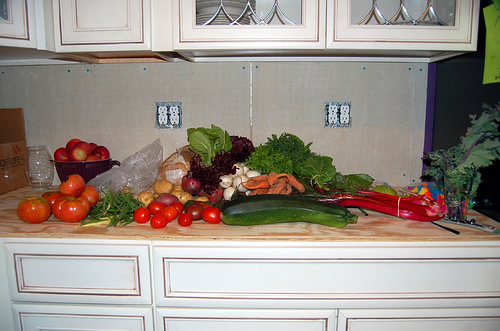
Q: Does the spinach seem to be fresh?
A: Yes, the spinach is fresh.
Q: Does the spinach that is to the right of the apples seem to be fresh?
A: Yes, the spinach is fresh.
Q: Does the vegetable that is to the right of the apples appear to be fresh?
A: Yes, the spinach is fresh.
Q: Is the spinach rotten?
A: No, the spinach is fresh.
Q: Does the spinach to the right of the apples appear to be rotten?
A: No, the spinach is fresh.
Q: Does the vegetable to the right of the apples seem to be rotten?
A: No, the spinach is fresh.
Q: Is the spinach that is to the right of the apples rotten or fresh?
A: The spinach is fresh.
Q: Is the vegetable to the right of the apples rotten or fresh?
A: The spinach is fresh.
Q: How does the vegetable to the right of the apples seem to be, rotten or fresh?
A: The spinach is fresh.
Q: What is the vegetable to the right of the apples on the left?
A: The vegetable is spinach.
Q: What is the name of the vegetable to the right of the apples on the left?
A: The vegetable is spinach.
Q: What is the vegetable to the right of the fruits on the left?
A: The vegetable is spinach.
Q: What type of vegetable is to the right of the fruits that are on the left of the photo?
A: The vegetable is spinach.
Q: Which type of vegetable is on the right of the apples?
A: The vegetable is spinach.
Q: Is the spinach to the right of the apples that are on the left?
A: Yes, the spinach is to the right of the apples.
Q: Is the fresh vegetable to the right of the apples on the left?
A: Yes, the spinach is to the right of the apples.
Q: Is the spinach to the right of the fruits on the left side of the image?
A: Yes, the spinach is to the right of the apples.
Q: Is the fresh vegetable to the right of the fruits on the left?
A: Yes, the spinach is to the right of the apples.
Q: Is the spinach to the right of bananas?
A: No, the spinach is to the right of the apples.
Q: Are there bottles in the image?
A: No, there are no bottles.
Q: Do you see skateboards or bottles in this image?
A: No, there are no bottles or skateboards.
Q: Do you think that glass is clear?
A: Yes, the glass is clear.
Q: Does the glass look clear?
A: Yes, the glass is clear.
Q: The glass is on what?
A: The glass is on the counter.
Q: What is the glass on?
A: The glass is on the counter.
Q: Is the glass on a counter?
A: Yes, the glass is on a counter.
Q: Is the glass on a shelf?
A: No, the glass is on a counter.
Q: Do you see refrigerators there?
A: Yes, there is a refrigerator.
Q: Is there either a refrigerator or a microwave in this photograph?
A: Yes, there is a refrigerator.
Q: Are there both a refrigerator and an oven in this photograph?
A: No, there is a refrigerator but no ovens.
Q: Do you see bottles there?
A: No, there are no bottles.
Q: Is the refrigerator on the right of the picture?
A: Yes, the refrigerator is on the right of the image.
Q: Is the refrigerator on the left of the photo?
A: No, the refrigerator is on the right of the image.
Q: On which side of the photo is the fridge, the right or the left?
A: The fridge is on the right of the image.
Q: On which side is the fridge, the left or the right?
A: The fridge is on the right of the image.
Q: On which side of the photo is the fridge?
A: The fridge is on the right of the image.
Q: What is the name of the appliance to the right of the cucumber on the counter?
A: The appliance is a refrigerator.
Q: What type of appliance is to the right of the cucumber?
A: The appliance is a refrigerator.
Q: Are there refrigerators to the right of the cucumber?
A: Yes, there is a refrigerator to the right of the cucumber.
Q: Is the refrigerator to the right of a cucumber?
A: Yes, the refrigerator is to the right of a cucumber.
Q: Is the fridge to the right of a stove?
A: No, the fridge is to the right of a cucumber.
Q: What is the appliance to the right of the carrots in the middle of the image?
A: The appliance is a refrigerator.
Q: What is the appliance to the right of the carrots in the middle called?
A: The appliance is a refrigerator.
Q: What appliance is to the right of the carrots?
A: The appliance is a refrigerator.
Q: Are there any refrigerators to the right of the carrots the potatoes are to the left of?
A: Yes, there is a refrigerator to the right of the carrots.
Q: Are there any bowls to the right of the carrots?
A: No, there is a refrigerator to the right of the carrots.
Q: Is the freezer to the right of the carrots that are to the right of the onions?
A: Yes, the freezer is to the right of the carrots.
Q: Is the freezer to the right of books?
A: No, the freezer is to the right of the carrots.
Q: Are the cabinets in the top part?
A: Yes, the cabinets are in the top of the image.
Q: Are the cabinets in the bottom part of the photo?
A: No, the cabinets are in the top of the image.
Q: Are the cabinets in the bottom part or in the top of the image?
A: The cabinets are in the top of the image.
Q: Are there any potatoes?
A: Yes, there are potatoes.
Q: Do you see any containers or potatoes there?
A: Yes, there are potatoes.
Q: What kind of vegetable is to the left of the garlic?
A: The vegetables are potatoes.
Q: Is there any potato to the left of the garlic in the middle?
A: Yes, there are potatoes to the left of the garlic.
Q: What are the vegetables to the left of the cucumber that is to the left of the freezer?
A: The vegetables are potatoes.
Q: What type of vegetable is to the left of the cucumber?
A: The vegetables are potatoes.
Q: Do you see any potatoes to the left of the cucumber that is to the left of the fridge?
A: Yes, there are potatoes to the left of the cucumber.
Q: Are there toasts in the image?
A: No, there are no toasts.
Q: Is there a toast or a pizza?
A: No, there are no toasts or pizzas.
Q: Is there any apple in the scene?
A: Yes, there are apples.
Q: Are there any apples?
A: Yes, there are apples.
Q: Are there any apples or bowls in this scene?
A: Yes, there are apples.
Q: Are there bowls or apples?
A: Yes, there are apples.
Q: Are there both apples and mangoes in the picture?
A: No, there are apples but no mangoes.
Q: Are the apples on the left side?
A: Yes, the apples are on the left of the image.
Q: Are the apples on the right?
A: No, the apples are on the left of the image.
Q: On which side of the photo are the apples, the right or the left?
A: The apples are on the left of the image.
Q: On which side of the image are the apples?
A: The apples are on the left of the image.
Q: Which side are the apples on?
A: The apples are on the left of the image.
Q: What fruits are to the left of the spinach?
A: The fruits are apples.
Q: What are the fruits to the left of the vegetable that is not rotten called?
A: The fruits are apples.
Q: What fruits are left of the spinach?
A: The fruits are apples.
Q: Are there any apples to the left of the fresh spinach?
A: Yes, there are apples to the left of the spinach.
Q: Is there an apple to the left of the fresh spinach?
A: Yes, there are apples to the left of the spinach.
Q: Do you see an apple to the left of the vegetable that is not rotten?
A: Yes, there are apples to the left of the spinach.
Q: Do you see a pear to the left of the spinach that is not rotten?
A: No, there are apples to the left of the spinach.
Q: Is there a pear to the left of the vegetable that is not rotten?
A: No, there are apples to the left of the spinach.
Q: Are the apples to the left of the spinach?
A: Yes, the apples are to the left of the spinach.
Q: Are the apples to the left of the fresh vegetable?
A: Yes, the apples are to the left of the spinach.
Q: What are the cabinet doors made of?
A: The cabinet doors are made of glass.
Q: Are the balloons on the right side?
A: Yes, the balloons are on the right of the image.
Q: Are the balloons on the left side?
A: No, the balloons are on the right of the image.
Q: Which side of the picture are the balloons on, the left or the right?
A: The balloons are on the right of the image.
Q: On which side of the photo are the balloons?
A: The balloons are on the right of the image.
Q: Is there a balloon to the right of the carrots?
A: Yes, there are balloons to the right of the carrots.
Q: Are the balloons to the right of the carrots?
A: Yes, the balloons are to the right of the carrots.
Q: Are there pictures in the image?
A: No, there are no pictures.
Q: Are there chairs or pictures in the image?
A: No, there are no pictures or chairs.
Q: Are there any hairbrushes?
A: No, there are no hairbrushes.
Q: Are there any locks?
A: No, there are no locks.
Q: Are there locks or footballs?
A: No, there are no locks or footballs.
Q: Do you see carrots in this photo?
A: Yes, there are carrots.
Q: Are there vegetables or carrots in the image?
A: Yes, there are carrots.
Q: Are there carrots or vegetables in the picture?
A: Yes, there are carrots.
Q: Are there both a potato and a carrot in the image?
A: Yes, there are both a carrot and a potato.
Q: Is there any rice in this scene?
A: No, there is no rice.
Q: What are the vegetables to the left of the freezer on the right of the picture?
A: The vegetables are carrots.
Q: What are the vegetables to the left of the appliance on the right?
A: The vegetables are carrots.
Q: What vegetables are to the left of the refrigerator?
A: The vegetables are carrots.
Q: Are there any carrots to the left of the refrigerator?
A: Yes, there are carrots to the left of the refrigerator.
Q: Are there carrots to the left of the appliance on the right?
A: Yes, there are carrots to the left of the refrigerator.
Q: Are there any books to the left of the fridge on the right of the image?
A: No, there are carrots to the left of the freezer.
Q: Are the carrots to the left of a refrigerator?
A: Yes, the carrots are to the left of a refrigerator.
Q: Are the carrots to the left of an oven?
A: No, the carrots are to the left of a refrigerator.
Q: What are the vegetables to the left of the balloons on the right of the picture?
A: The vegetables are carrots.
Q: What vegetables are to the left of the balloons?
A: The vegetables are carrots.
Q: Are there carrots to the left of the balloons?
A: Yes, there are carrots to the left of the balloons.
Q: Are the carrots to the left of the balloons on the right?
A: Yes, the carrots are to the left of the balloons.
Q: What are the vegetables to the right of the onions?
A: The vegetables are carrots.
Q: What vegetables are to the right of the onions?
A: The vegetables are carrots.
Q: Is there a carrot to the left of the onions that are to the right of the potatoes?
A: No, the carrots are to the right of the onions.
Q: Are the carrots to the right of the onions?
A: Yes, the carrots are to the right of the onions.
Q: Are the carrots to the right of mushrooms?
A: No, the carrots are to the right of the onions.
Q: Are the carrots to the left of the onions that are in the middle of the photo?
A: No, the carrots are to the right of the onions.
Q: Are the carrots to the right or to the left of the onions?
A: The carrots are to the right of the onions.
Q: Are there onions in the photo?
A: Yes, there are onions.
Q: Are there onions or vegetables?
A: Yes, there are onions.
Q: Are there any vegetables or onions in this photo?
A: Yes, there are onions.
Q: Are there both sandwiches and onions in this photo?
A: No, there are onions but no sandwiches.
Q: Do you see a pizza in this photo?
A: No, there are no pizzas.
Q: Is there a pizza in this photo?
A: No, there are no pizzas.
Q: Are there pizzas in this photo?
A: No, there are no pizzas.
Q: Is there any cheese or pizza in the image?
A: No, there are no pizzas or cheese.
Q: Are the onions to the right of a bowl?
A: No, the onions are to the right of a tomato.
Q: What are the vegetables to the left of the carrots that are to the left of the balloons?
A: The vegetables are onions.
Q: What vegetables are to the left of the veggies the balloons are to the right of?
A: The vegetables are onions.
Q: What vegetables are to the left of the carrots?
A: The vegetables are onions.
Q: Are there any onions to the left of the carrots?
A: Yes, there are onions to the left of the carrots.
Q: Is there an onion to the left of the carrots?
A: Yes, there are onions to the left of the carrots.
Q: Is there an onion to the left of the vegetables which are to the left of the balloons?
A: Yes, there are onions to the left of the carrots.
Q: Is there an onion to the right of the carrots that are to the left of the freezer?
A: No, the onions are to the left of the carrots.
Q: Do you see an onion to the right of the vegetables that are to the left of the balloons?
A: No, the onions are to the left of the carrots.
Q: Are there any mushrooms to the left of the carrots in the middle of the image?
A: No, there are onions to the left of the carrots.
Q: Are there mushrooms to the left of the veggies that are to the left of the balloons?
A: No, there are onions to the left of the carrots.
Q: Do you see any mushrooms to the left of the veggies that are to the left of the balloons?
A: No, there are onions to the left of the carrots.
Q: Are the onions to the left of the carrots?
A: Yes, the onions are to the left of the carrots.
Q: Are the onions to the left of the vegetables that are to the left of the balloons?
A: Yes, the onions are to the left of the carrots.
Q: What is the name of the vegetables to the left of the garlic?
A: The vegetables are onions.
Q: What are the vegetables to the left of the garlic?
A: The vegetables are onions.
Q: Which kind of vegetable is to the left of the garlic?
A: The vegetables are onions.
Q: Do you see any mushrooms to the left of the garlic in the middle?
A: No, there are onions to the left of the garlic.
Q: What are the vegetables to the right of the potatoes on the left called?
A: The vegetables are onions.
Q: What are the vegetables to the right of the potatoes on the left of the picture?
A: The vegetables are onions.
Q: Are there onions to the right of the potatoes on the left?
A: Yes, there are onions to the right of the potatoes.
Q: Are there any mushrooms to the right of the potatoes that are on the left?
A: No, there are onions to the right of the potatoes.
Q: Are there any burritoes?
A: No, there are no burritoes.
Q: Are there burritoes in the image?
A: No, there are no burritoes.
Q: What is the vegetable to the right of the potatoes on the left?
A: The vegetable is garlic.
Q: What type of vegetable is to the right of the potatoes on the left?
A: The vegetable is garlic.